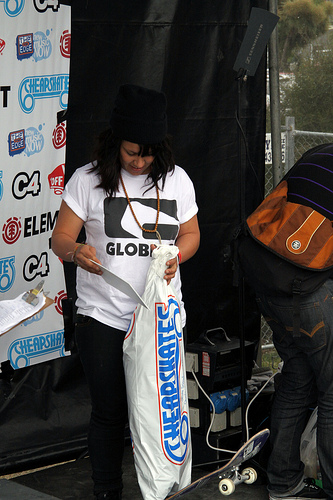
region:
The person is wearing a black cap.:
[112, 91, 178, 141]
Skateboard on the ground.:
[174, 434, 262, 481]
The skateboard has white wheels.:
[224, 474, 255, 487]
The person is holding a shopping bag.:
[68, 154, 189, 285]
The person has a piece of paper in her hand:
[83, 255, 147, 316]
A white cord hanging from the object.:
[196, 359, 268, 437]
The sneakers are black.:
[269, 463, 320, 499]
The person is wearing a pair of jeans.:
[259, 302, 328, 471]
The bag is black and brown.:
[241, 182, 321, 294]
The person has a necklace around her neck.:
[115, 175, 168, 247]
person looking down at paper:
[82, 89, 186, 495]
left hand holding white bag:
[132, 248, 191, 498]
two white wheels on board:
[212, 467, 256, 491]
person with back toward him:
[267, 312, 332, 490]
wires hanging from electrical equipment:
[191, 364, 269, 445]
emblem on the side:
[3, 326, 68, 364]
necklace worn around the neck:
[110, 170, 167, 239]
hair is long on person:
[106, 135, 177, 184]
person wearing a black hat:
[110, 89, 170, 143]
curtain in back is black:
[72, 9, 254, 90]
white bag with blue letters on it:
[123, 245, 191, 497]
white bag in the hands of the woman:
[120, 244, 192, 498]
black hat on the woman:
[110, 84, 164, 142]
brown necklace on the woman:
[116, 170, 163, 235]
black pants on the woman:
[73, 312, 127, 499]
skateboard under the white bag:
[125, 426, 271, 499]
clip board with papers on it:
[0, 279, 55, 337]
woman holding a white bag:
[51, 83, 199, 499]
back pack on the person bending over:
[226, 139, 332, 297]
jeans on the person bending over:
[255, 284, 332, 499]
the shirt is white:
[57, 156, 187, 321]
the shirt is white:
[32, 159, 246, 428]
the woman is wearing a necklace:
[85, 133, 202, 290]